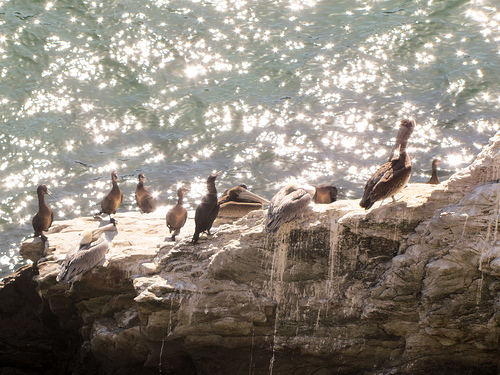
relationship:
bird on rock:
[30, 182, 55, 230] [7, 136, 496, 371]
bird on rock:
[17, 229, 56, 274] [7, 136, 496, 371]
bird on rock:
[55, 216, 121, 286] [7, 136, 496, 371]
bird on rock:
[96, 169, 127, 214] [7, 136, 496, 371]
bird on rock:
[130, 170, 159, 213] [7, 136, 496, 371]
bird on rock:
[161, 183, 191, 241] [7, 136, 496, 371]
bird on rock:
[187, 172, 225, 244] [7, 136, 496, 371]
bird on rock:
[357, 111, 416, 212] [7, 136, 496, 371]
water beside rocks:
[6, 3, 497, 189] [1, 136, 495, 368]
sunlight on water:
[28, 39, 106, 114] [6, 3, 497, 189]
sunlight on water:
[293, 53, 384, 150] [6, 3, 497, 189]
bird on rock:
[187, 173, 224, 248] [0, 129, 500, 375]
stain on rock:
[285, 227, 330, 279] [6, 167, 494, 372]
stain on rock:
[347, 231, 405, 263] [6, 167, 494, 372]